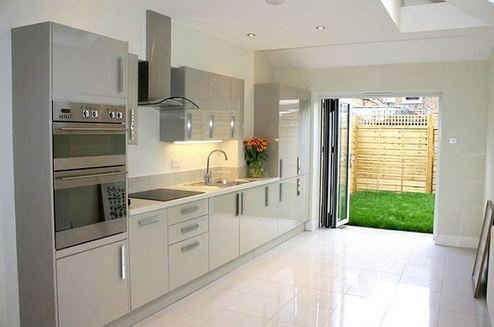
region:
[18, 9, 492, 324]
a brand new kitchen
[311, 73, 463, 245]
doors leading to the outside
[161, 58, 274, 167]
cupboards above kitchen sink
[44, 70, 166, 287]
a double oven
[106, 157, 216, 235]
stove top range on counter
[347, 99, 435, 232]
a brown privacy fence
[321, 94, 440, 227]
doors open to the back yard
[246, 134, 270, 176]
flowering potted plant on counter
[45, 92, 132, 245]
oven for cooking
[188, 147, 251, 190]
sink with pot filling faucet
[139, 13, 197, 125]
exhaust fan for stovetop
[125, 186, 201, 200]
flattop stove surface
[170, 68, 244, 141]
chrome cabinets over sink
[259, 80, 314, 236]
tall set of chrome finished cabinets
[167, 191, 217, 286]
stack of drawers for storage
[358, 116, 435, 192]
tall wooden fence for back yard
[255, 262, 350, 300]
shiny white kitchen floor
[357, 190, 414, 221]
lush green grass in the yard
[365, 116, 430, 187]
tall brown fence in the backyard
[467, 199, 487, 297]
picture leaning against the wall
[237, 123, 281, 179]
vase filled with flowers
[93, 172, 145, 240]
towel on the door of the stove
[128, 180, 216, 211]
gray mat on counter top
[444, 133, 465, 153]
outlet on the wall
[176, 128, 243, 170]
light under the sink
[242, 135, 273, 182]
Flowers are in a vase.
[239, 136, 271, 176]
The flowers are pink.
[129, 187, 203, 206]
A mat is by the sink.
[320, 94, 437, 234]
The door is open.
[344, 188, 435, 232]
The grass is neatly cut.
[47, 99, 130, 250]
The stove is built-in.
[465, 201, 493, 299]
A mirror is leaning against the cabinet.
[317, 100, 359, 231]
The doors slide open and closed.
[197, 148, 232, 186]
The faucet is metal.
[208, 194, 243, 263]
The cabinet is white.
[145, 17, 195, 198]
the overhead over the stove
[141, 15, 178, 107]
the overhead is silver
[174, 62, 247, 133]
the cabinets are silver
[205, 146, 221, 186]
the faucet is silver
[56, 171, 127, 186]
the handle on the stove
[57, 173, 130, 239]
the stove is silver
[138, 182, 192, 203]
the stove is black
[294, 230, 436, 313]
the floor is white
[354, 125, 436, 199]
the fence is wooden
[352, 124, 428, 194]
the fence is tan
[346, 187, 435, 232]
A well-manicured area of green grass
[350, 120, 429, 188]
Wooden privacy fence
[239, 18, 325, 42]
Recessed ceiling lights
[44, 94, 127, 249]
Stainless steel double oven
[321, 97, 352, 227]
open folding door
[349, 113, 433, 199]
wood privacy fence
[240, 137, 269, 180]
orange flowers sitting on the counter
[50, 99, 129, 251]
double stainless steel oven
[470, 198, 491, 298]
framed picture leaning against a wall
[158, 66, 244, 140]
gleaming stainless steel cabinets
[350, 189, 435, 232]
small patch of green grass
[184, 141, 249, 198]
sink and silver faucet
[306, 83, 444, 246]
open doorway leading to yard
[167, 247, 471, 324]
shiny white tile floor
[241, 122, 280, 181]
vase with pink and green flowers